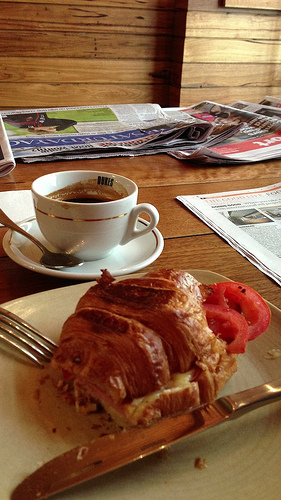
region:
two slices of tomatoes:
[202, 279, 271, 350]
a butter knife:
[13, 378, 279, 494]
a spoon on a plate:
[0, 208, 83, 279]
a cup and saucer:
[1, 169, 167, 284]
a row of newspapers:
[1, 101, 278, 179]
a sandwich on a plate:
[50, 264, 232, 419]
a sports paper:
[184, 99, 280, 163]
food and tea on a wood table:
[7, 172, 279, 416]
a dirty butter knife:
[8, 412, 192, 484]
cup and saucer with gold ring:
[11, 167, 170, 283]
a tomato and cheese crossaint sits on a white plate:
[34, 269, 262, 424]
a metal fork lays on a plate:
[62, 429, 226, 467]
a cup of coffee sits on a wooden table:
[0, 169, 163, 276]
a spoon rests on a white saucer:
[3, 212, 76, 268]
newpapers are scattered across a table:
[12, 109, 267, 166]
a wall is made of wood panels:
[0, 1, 250, 99]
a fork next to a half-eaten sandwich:
[3, 305, 53, 368]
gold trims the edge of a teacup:
[51, 215, 116, 221]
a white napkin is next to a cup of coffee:
[5, 191, 31, 220]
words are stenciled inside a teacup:
[96, 175, 119, 188]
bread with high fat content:
[27, 267, 231, 432]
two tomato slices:
[194, 273, 269, 357]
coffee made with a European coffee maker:
[17, 162, 150, 265]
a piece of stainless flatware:
[14, 375, 272, 499]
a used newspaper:
[1, 95, 211, 168]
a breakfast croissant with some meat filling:
[20, 265, 243, 464]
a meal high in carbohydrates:
[23, 267, 255, 452]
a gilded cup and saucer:
[0, 169, 167, 288]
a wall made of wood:
[9, 3, 277, 110]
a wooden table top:
[0, 147, 264, 308]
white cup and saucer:
[2, 162, 164, 278]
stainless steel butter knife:
[10, 379, 279, 498]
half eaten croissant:
[50, 259, 280, 438]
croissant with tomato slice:
[50, 263, 272, 435]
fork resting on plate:
[1, 266, 280, 497]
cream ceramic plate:
[1, 266, 275, 497]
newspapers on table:
[0, 97, 280, 310]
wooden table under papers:
[1, 95, 279, 311]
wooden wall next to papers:
[0, 0, 280, 177]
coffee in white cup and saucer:
[32, 167, 159, 260]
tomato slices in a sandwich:
[201, 281, 270, 354]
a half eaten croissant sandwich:
[51, 266, 270, 429]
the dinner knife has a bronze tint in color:
[10, 378, 280, 498]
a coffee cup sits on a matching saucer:
[30, 169, 158, 260]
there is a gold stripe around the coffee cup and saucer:
[32, 206, 127, 221]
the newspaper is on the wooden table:
[175, 181, 280, 287]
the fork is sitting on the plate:
[0, 306, 59, 369]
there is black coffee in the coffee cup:
[63, 196, 112, 202]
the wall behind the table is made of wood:
[0, 0, 280, 106]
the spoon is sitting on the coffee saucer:
[0, 206, 83, 267]